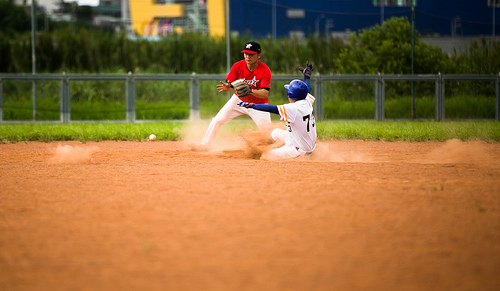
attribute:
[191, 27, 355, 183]
people — playing baseball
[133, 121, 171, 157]
ball — white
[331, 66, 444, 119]
fence — metal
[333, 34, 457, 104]
bushes — line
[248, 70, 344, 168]
player — sliding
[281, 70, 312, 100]
helmet — blue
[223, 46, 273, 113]
shirt — red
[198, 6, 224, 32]
part — yellow painted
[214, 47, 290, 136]
person — playing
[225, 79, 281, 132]
sleeve — blue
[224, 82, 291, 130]
sleeve — blue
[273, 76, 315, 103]
helmet — blue baseball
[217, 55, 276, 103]
shirt — red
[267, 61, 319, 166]
player — sliding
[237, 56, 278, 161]
player — waiting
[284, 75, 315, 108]
helmet — blue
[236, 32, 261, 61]
hat — black red and white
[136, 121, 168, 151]
baseball — traveling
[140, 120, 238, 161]
dust — created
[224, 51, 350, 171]
player — sliding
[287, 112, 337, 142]
numbers — black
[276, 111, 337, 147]
jersey — white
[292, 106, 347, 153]
numbers — black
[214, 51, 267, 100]
jersey — red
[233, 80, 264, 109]
letters — white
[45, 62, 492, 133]
fence — background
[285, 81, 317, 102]
helmet — blue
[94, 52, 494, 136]
fence — metal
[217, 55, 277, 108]
jersey — red 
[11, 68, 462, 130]
pole — grey wide fence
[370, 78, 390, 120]
pole — grey wide fence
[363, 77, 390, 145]
pole — grey wide fence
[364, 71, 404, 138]
pole — grey wide fence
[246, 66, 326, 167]
player — baseball 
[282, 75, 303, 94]
helmet — blue 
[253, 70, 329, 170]
player — baseball 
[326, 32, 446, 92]
bush — green 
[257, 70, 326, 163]
player — baseball 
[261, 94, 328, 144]
jersey — white 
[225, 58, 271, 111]
jersey — red short sleeve 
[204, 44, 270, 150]
player — baseball 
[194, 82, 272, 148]
pants — white 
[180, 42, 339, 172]
player — baseball , clay field 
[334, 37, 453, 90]
hedge — green 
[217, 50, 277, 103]
shirt — red 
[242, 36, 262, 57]
cap — red , black 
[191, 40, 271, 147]
person —  standing up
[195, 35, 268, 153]
player —  standing up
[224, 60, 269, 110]
shirt — red, white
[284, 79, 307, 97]
baseball helmet — blue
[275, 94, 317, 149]
baseball jersey — white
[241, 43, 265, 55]
hat — black, red